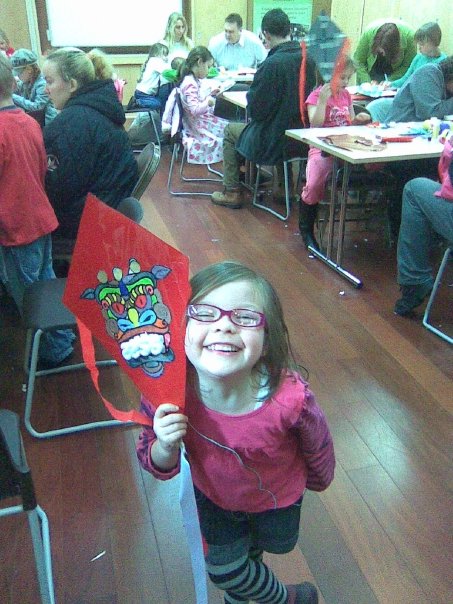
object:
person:
[38, 45, 141, 284]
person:
[393, 120, 453, 317]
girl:
[173, 40, 234, 169]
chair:
[166, 89, 236, 199]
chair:
[313, 104, 397, 258]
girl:
[297, 54, 363, 260]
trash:
[88, 542, 110, 566]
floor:
[9, 164, 453, 596]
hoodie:
[37, 78, 142, 242]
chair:
[37, 107, 162, 277]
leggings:
[204, 551, 287, 604]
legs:
[393, 174, 453, 320]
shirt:
[132, 362, 337, 515]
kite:
[59, 190, 189, 424]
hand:
[151, 399, 191, 452]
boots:
[297, 195, 321, 255]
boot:
[209, 180, 245, 209]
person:
[206, 9, 308, 213]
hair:
[44, 43, 120, 92]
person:
[349, 17, 422, 91]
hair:
[162, 9, 195, 55]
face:
[183, 274, 266, 379]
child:
[134, 258, 337, 602]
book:
[208, 78, 235, 98]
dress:
[179, 78, 239, 165]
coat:
[41, 76, 140, 239]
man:
[208, 9, 269, 73]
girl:
[130, 40, 178, 111]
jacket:
[351, 20, 421, 88]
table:
[221, 87, 451, 117]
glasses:
[183, 298, 268, 329]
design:
[78, 254, 178, 381]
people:
[161, 7, 199, 79]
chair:
[24, 195, 145, 440]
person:
[0, 50, 80, 371]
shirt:
[0, 104, 60, 250]